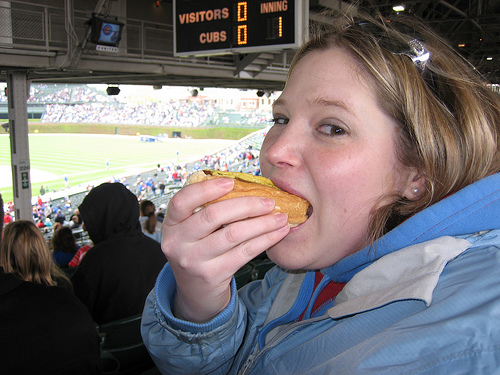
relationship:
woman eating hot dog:
[138, 10, 500, 375] [186, 168, 312, 230]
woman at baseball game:
[138, 10, 500, 375] [1, 124, 265, 201]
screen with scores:
[173, 0, 311, 58] [233, 0, 252, 46]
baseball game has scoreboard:
[1, 124, 265, 201] [174, 1, 310, 58]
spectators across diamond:
[2, 84, 277, 125] [1, 123, 243, 203]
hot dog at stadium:
[186, 168, 312, 230] [4, 3, 499, 375]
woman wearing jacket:
[138, 10, 500, 375] [139, 172, 500, 373]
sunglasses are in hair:
[354, 18, 432, 72] [286, 13, 500, 263]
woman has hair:
[138, 10, 500, 375] [286, 13, 500, 263]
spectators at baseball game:
[2, 84, 277, 125] [1, 124, 265, 201]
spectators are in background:
[2, 84, 277, 125] [1, 84, 280, 233]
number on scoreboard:
[237, 2, 250, 46] [174, 1, 310, 58]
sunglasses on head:
[354, 18, 432, 72] [259, 10, 499, 271]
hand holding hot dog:
[159, 178, 292, 291] [186, 168, 312, 230]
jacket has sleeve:
[139, 172, 500, 373] [138, 263, 271, 373]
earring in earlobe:
[412, 188, 422, 195] [404, 171, 425, 202]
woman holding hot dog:
[138, 10, 500, 375] [186, 168, 312, 230]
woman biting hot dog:
[138, 10, 500, 375] [186, 168, 312, 230]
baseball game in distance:
[1, 124, 265, 201] [1, 84, 283, 204]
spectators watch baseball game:
[2, 84, 277, 125] [1, 124, 265, 201]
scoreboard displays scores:
[174, 1, 310, 58] [233, 0, 252, 46]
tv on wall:
[90, 14, 127, 47] [1, 0, 340, 81]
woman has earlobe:
[138, 10, 500, 375] [404, 171, 425, 202]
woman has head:
[138, 10, 500, 375] [259, 10, 499, 271]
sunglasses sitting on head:
[354, 18, 432, 72] [259, 10, 499, 271]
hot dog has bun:
[186, 168, 312, 230] [186, 168, 311, 230]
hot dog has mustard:
[186, 168, 312, 230] [211, 169, 239, 180]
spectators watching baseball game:
[2, 84, 277, 125] [1, 124, 265, 201]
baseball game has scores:
[1, 124, 265, 201] [233, 0, 252, 46]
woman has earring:
[138, 10, 500, 375] [412, 188, 422, 195]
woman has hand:
[138, 10, 500, 375] [159, 178, 292, 291]